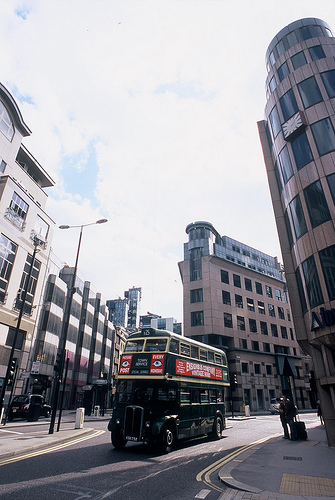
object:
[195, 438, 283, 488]
yellow lines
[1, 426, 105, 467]
yellow lines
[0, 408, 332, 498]
road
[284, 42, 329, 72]
windows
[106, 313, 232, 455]
bus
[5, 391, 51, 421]
car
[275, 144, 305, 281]
wall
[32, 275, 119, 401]
wall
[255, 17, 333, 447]
building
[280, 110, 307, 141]
clock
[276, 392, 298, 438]
man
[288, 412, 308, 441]
suitcase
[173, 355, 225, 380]
sign